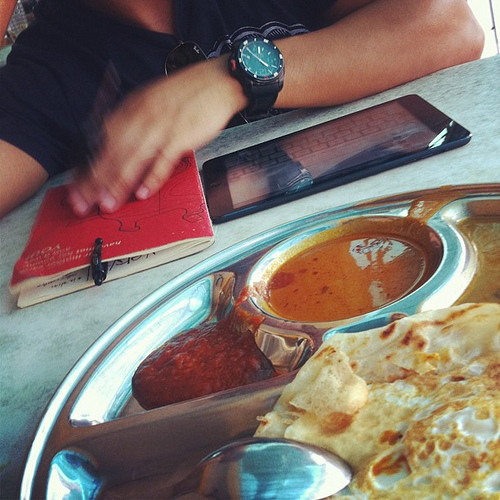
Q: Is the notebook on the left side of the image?
A: Yes, the notebook is on the left of the image.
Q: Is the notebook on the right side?
A: No, the notebook is on the left of the image.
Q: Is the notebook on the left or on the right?
A: The notebook is on the left of the image.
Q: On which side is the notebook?
A: The notebook is on the left of the image.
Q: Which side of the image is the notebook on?
A: The notebook is on the left of the image.